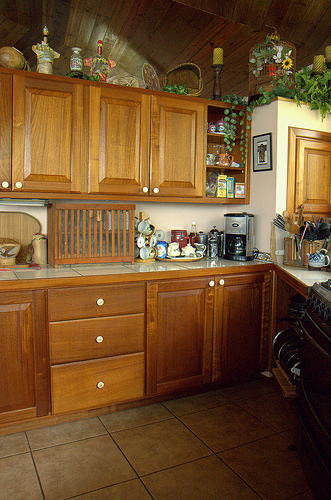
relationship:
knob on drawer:
[96, 297, 104, 305] [46, 280, 145, 320]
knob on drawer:
[95, 334, 103, 343] [46, 313, 144, 363]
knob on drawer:
[95, 380, 104, 388] [51, 350, 145, 413]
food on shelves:
[208, 172, 245, 198] [204, 128, 243, 202]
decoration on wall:
[252, 132, 272, 173] [0, 95, 330, 261]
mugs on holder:
[137, 220, 159, 258] [138, 208, 153, 265]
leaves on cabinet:
[226, 106, 256, 155] [137, 91, 250, 201]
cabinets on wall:
[0, 61, 254, 212] [253, 178, 284, 210]